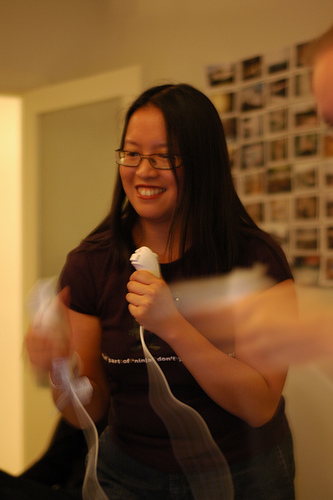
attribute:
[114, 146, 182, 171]
glasses — dark rimmed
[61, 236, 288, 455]
shirt — black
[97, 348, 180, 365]
lettering — white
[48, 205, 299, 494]
tshirt — black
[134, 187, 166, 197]
teeth — white, straight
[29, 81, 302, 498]
woman — smiling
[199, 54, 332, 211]
wall photos — small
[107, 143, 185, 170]
framed glasses — wire-framed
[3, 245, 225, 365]
controllers — video game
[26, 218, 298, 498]
shirt — black, white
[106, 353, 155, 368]
text — white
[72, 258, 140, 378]
t-shirt — graphic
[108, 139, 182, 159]
eyebrows — dark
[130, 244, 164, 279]
controller — gaming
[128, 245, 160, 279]
controller — white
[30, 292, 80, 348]
controller — video game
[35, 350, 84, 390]
wrap — wrist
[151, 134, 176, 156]
eyebrow — dark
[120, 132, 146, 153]
eyebrow — dark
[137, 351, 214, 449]
wire — white